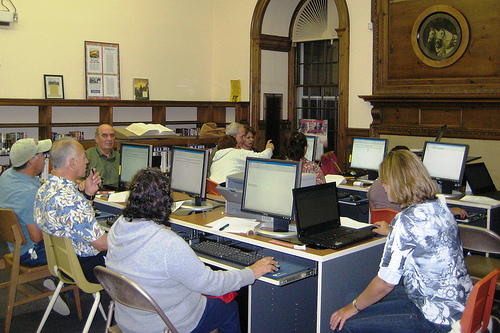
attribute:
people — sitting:
[26, 115, 483, 269]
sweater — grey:
[115, 211, 192, 323]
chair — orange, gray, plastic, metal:
[467, 272, 489, 332]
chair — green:
[39, 231, 100, 308]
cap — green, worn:
[11, 137, 53, 162]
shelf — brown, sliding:
[21, 104, 111, 129]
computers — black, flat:
[244, 155, 295, 226]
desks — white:
[153, 172, 388, 281]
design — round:
[412, 4, 479, 73]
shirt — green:
[90, 147, 125, 191]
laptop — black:
[290, 193, 371, 251]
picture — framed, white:
[138, 82, 148, 95]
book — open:
[124, 121, 185, 139]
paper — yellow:
[230, 73, 248, 106]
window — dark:
[303, 47, 340, 113]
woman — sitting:
[98, 161, 214, 332]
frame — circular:
[403, 3, 481, 73]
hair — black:
[132, 168, 167, 216]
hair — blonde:
[380, 144, 439, 197]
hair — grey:
[54, 137, 76, 167]